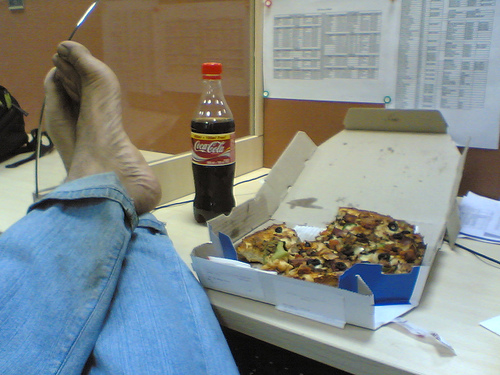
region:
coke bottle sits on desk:
[187, 61, 237, 224]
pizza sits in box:
[230, 204, 427, 297]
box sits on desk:
[188, 102, 473, 332]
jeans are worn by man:
[0, 171, 238, 374]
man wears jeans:
[1, 39, 238, 374]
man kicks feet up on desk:
[3, 39, 239, 374]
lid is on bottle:
[200, 58, 220, 80]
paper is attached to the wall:
[258, 1, 498, 152]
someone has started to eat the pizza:
[237, 204, 424, 289]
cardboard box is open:
[189, 101, 472, 328]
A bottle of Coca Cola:
[184, 56, 242, 226]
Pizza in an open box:
[188, 102, 471, 340]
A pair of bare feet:
[39, 39, 165, 218]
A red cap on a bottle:
[195, 56, 226, 83]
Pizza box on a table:
[151, 103, 498, 373]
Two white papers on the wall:
[258, 1, 498, 155]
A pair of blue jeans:
[0, 168, 240, 372]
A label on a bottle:
[187, 126, 239, 169]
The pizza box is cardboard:
[188, 104, 469, 334]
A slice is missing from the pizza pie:
[237, 203, 428, 288]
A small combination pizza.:
[237, 208, 424, 287]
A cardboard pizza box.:
[191, 107, 471, 329]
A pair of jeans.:
[0, 170, 238, 373]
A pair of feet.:
[43, 38, 163, 213]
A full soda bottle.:
[191, 61, 236, 220]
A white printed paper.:
[261, 0, 401, 102]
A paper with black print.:
[387, 0, 499, 150]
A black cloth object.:
[1, 83, 37, 168]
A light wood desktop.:
[207, 240, 499, 374]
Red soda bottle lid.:
[201, 59, 224, 75]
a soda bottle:
[191, 66, 246, 203]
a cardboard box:
[335, 164, 405, 201]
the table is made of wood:
[441, 292, 473, 329]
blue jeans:
[121, 297, 213, 372]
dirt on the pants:
[70, 210, 123, 285]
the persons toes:
[53, 41, 81, 64]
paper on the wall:
[276, 14, 385, 93]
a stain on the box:
[293, 194, 326, 211]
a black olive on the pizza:
[358, 231, 373, 243]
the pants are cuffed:
[88, 172, 119, 199]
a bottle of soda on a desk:
[190, 63, 237, 227]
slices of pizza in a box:
[236, 207, 423, 285]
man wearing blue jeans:
[1, 171, 240, 373]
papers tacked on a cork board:
[263, 0, 497, 150]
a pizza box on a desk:
[191, 107, 467, 329]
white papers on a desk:
[455, 190, 497, 244]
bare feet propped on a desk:
[44, 40, 159, 209]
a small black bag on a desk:
[1, 85, 29, 160]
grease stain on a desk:
[386, 320, 454, 361]